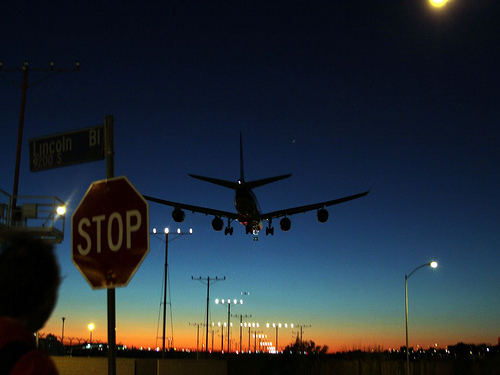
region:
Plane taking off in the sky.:
[136, 140, 381, 251]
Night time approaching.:
[300, 72, 481, 177]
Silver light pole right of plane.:
[385, 233, 456, 362]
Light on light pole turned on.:
[418, 254, 449, 281]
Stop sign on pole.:
[58, 170, 160, 297]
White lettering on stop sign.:
[68, 203, 149, 265]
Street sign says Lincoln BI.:
[22, 127, 114, 162]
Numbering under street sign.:
[26, 149, 71, 170]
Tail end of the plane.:
[233, 128, 254, 180]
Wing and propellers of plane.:
[270, 183, 380, 244]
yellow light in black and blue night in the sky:
[422, 1, 454, 13]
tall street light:
[391, 245, 451, 355]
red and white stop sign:
[64, 169, 158, 374]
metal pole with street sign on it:
[98, 291, 129, 372]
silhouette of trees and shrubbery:
[66, 325, 496, 363]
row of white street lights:
[150, 223, 306, 371]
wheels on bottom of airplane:
[168, 206, 238, 241]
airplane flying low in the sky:
[148, 123, 380, 252]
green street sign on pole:
[20, 119, 119, 176]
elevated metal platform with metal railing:
[3, 186, 67, 248]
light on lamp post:
[404, 259, 440, 372]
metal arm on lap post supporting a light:
[407, 260, 429, 283]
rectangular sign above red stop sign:
[26, 124, 108, 177]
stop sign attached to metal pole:
[102, 116, 124, 373]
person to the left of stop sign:
[2, 229, 61, 374]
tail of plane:
[187, 129, 292, 191]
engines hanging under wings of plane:
[279, 216, 293, 232]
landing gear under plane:
[223, 214, 238, 236]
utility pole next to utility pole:
[147, 226, 194, 349]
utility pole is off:
[189, 274, 224, 351]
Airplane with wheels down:
[135, 133, 370, 239]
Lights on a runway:
[150, 226, 298, 362]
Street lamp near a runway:
[402, 259, 438, 372]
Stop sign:
[69, 175, 151, 373]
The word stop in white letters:
[75, 206, 142, 253]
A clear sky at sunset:
[0, 0, 498, 353]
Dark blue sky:
[0, 66, 496, 248]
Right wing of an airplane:
[258, 185, 368, 222]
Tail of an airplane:
[185, 132, 292, 187]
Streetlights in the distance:
[33, 319, 498, 361]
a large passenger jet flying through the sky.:
[139, 139, 386, 239]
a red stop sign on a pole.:
[61, 171, 167, 293]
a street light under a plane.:
[386, 254, 443, 354]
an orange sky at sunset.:
[35, 320, 497, 345]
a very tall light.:
[207, 284, 254, 352]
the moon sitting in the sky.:
[409, 0, 454, 20]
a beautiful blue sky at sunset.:
[0, 3, 495, 330]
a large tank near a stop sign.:
[1, 194, 69, 373]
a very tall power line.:
[151, 261, 185, 368]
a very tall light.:
[58, 310, 75, 347]